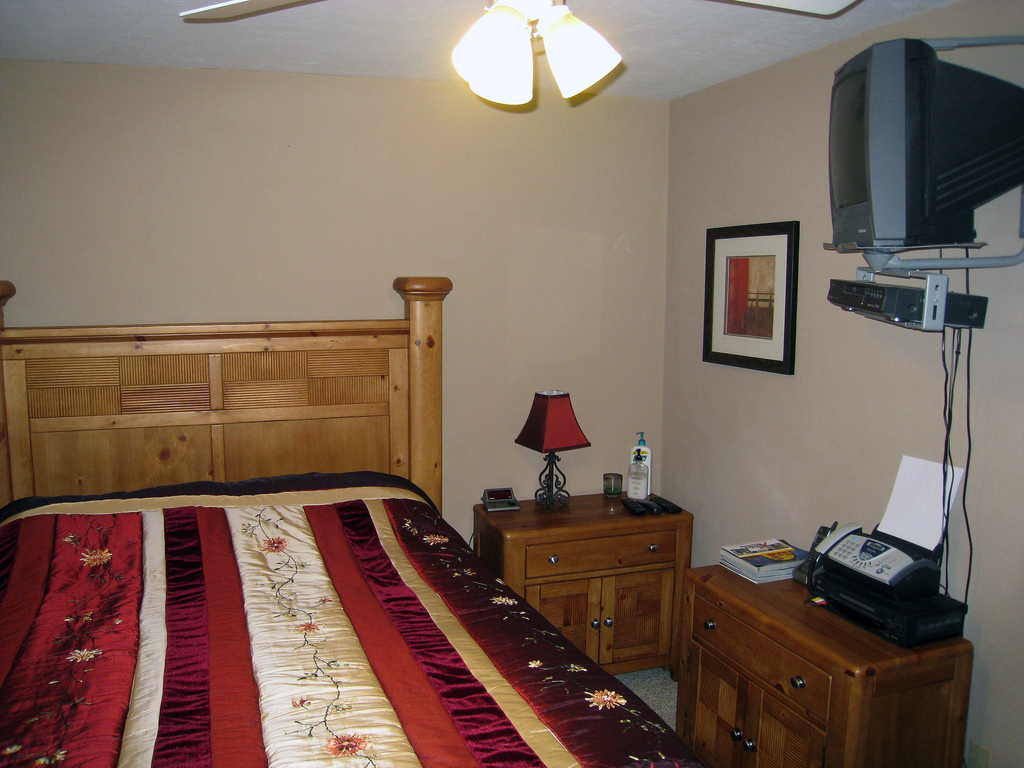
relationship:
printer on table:
[811, 525, 967, 655] [670, 550, 977, 766]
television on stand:
[788, 13, 1019, 258] [827, 241, 992, 298]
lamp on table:
[505, 377, 611, 527] [453, 471, 722, 664]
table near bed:
[460, 479, 685, 669] [0, 273, 667, 765]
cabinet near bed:
[666, 541, 976, 765] [0, 273, 667, 765]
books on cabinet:
[705, 531, 829, 589] [657, 531, 990, 766]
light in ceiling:
[424, 0, 633, 130] [6, 0, 977, 130]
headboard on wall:
[0, 269, 479, 495] [0, 60, 671, 495]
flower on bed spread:
[575, 668, 640, 729] [9, 445, 640, 766]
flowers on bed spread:
[398, 529, 498, 627] [16, 477, 652, 766]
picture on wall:
[698, 203, 861, 401] [661, 134, 841, 467]